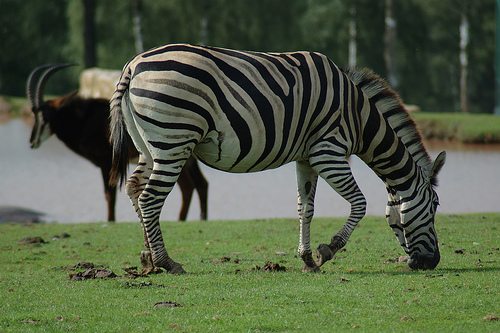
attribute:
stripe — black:
[151, 167, 181, 178]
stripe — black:
[148, 178, 178, 190]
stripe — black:
[154, 155, 192, 166]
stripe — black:
[149, 135, 200, 150]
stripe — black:
[128, 105, 204, 138]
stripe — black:
[127, 83, 218, 135]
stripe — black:
[135, 59, 252, 173]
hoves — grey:
[292, 241, 340, 270]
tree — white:
[453, 17, 474, 115]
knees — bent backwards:
[169, 158, 213, 227]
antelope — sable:
[18, 58, 230, 220]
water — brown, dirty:
[0, 95, 500, 217]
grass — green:
[200, 230, 279, 257]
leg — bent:
[314, 162, 365, 262]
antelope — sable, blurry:
[21, 59, 211, 221]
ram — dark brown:
[21, 56, 225, 247]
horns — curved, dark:
[9, 45, 96, 137]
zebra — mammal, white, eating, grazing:
[107, 44, 446, 276]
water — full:
[455, 178, 497, 204]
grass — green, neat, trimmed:
[3, 214, 498, 331]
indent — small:
[152, 300, 180, 311]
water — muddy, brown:
[1, 114, 499, 224]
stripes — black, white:
[209, 57, 294, 127]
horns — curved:
[22, 56, 79, 113]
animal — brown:
[29, 73, 144, 180]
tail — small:
[108, 72, 129, 184]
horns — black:
[24, 56, 85, 149]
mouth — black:
[409, 252, 442, 271]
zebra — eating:
[71, 40, 466, 282]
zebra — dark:
[91, 40, 481, 300]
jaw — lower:
[380, 181, 437, 274]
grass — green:
[241, 249, 305, 331]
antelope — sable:
[27, 51, 87, 153]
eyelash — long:
[428, 166, 446, 225]